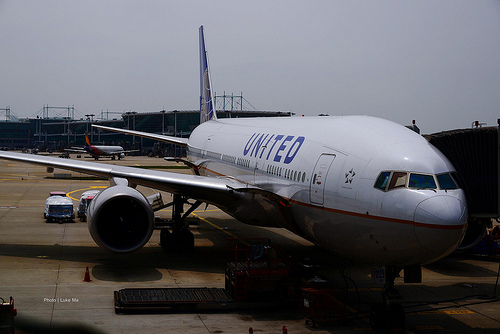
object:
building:
[1, 103, 493, 228]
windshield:
[369, 166, 472, 198]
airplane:
[64, 130, 140, 161]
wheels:
[159, 226, 196, 257]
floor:
[5, 223, 85, 318]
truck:
[78, 189, 101, 222]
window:
[374, 170, 392, 191]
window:
[388, 169, 409, 191]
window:
[408, 172, 438, 189]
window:
[434, 172, 459, 189]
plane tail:
[198, 24, 216, 123]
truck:
[181, 224, 314, 299]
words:
[239, 130, 305, 167]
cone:
[82, 265, 93, 283]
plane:
[1, 22, 498, 332]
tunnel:
[420, 124, 498, 219]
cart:
[43, 191, 75, 223]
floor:
[12, 221, 90, 309]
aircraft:
[0, 24, 500, 308]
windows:
[186, 144, 308, 182]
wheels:
[380, 285, 401, 319]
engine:
[85, 183, 155, 255]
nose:
[412, 193, 470, 254]